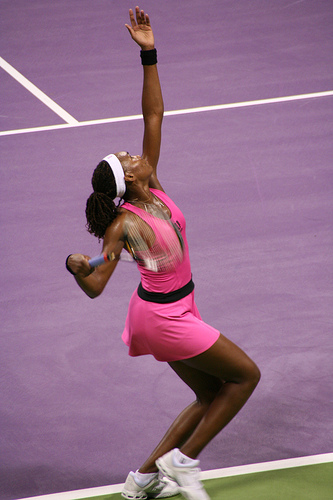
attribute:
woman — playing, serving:
[61, 140, 263, 450]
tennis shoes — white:
[113, 459, 233, 497]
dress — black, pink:
[122, 222, 195, 366]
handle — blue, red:
[89, 253, 120, 273]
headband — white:
[100, 153, 126, 198]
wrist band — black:
[133, 50, 159, 71]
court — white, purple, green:
[19, 48, 332, 354]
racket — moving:
[74, 220, 186, 278]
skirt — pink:
[124, 301, 230, 368]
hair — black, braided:
[78, 173, 125, 241]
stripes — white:
[17, 71, 328, 133]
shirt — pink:
[124, 221, 191, 293]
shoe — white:
[161, 453, 203, 496]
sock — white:
[174, 449, 195, 467]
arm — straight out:
[123, 52, 168, 162]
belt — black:
[127, 283, 220, 309]